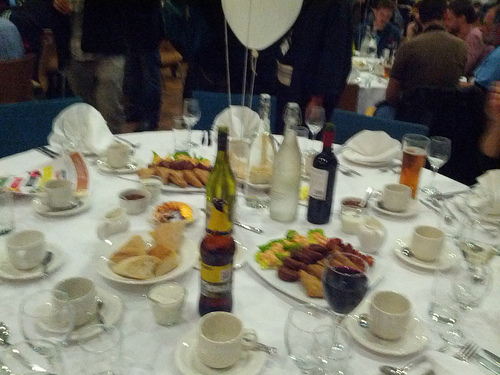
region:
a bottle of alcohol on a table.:
[199, 117, 239, 236]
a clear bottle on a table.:
[262, 97, 310, 232]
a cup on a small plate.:
[397, 221, 460, 267]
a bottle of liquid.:
[181, 206, 252, 332]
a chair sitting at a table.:
[382, 30, 486, 170]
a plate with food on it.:
[93, 205, 199, 292]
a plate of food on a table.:
[135, 143, 230, 196]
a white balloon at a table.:
[211, 0, 308, 103]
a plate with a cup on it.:
[29, 266, 126, 349]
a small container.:
[150, 258, 187, 317]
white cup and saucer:
[353, 289, 423, 374]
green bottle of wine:
[193, 114, 243, 248]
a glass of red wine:
[300, 246, 372, 367]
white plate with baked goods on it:
[112, 207, 208, 307]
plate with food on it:
[251, 215, 348, 315]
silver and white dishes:
[345, 295, 480, 374]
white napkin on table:
[48, 94, 132, 154]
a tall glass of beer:
[393, 112, 444, 222]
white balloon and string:
[204, 2, 314, 154]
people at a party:
[26, 11, 488, 161]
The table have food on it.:
[251, 217, 388, 311]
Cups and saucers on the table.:
[18, 210, 111, 357]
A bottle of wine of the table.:
[200, 122, 242, 241]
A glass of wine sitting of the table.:
[406, 131, 465, 206]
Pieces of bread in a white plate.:
[94, 212, 202, 303]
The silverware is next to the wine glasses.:
[419, 308, 490, 354]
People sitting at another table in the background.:
[324, 17, 489, 104]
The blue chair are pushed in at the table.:
[167, 77, 276, 129]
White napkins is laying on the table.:
[48, 98, 125, 150]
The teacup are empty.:
[186, 319, 258, 364]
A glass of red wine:
[308, 244, 378, 352]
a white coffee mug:
[180, 307, 288, 369]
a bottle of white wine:
[195, 115, 248, 250]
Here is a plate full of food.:
[252, 217, 380, 304]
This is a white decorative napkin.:
[39, 97, 130, 170]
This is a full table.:
[2, 85, 498, 374]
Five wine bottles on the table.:
[150, 71, 372, 298]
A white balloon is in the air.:
[211, 3, 324, 63]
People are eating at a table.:
[304, 17, 498, 122]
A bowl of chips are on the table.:
[97, 209, 189, 287]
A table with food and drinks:
[6, 100, 496, 373]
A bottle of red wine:
[305, 118, 341, 224]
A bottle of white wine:
[202, 120, 244, 236]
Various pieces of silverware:
[381, 333, 495, 370]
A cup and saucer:
[171, 310, 275, 372]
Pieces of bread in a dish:
[97, 223, 194, 280]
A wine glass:
[179, 92, 203, 150]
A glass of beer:
[396, 130, 431, 201]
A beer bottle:
[194, 193, 246, 314]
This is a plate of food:
[256, 227, 373, 294]